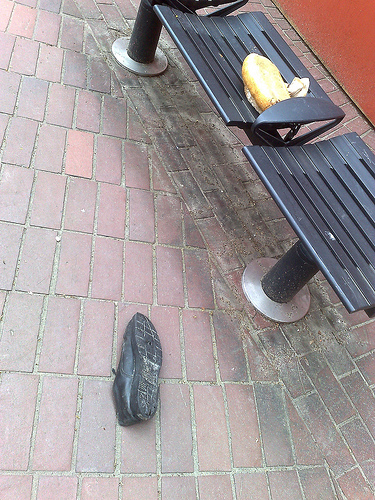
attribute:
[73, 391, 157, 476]
brick — red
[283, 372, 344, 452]
brick — red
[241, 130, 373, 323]
bench — sitting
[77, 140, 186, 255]
brick — red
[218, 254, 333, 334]
plate — silver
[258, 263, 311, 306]
legs — black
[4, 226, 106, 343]
ground — rectangular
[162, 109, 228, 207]
bricks — dirty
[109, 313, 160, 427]
shoe — dirty, upsided down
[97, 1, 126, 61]
brick — cracked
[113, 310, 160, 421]
shoe — black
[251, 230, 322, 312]
post — metal 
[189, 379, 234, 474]
brick — red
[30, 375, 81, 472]
brick — red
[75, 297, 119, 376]
brick — red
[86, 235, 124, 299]
brick — red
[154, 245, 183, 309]
brick — red